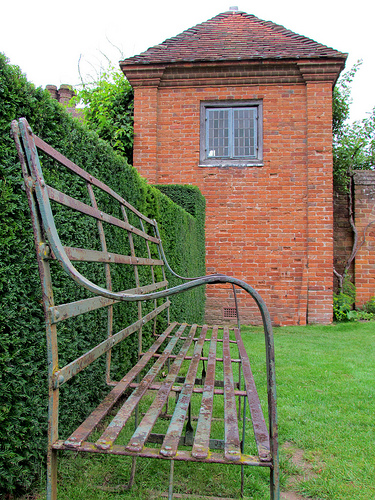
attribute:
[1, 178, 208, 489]
hedge — green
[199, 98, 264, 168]
window — small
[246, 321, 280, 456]
slat — metal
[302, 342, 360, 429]
grass — green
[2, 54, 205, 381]
hedge — well trimmed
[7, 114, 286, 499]
bench — bare, metal, metalic, rusty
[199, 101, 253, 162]
window — closed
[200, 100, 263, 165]
window — shuttered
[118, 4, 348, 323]
building — red, brick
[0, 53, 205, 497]
hedge — green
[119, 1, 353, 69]
roof — worn, tile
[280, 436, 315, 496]
patch — bare, gray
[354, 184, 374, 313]
wall — brick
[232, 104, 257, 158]
window — glass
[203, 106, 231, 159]
window — glass